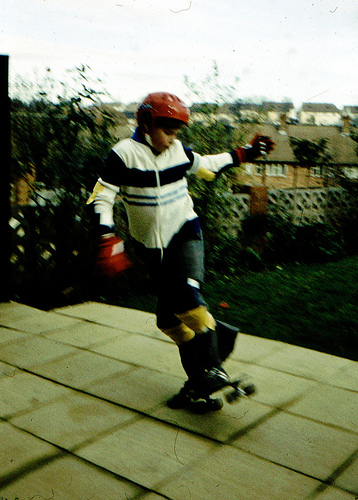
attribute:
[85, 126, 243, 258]
sweater — long sleeved, striped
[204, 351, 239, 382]
shoe — boy's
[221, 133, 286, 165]
hand — his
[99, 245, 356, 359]
grass — green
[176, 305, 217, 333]
kneepad — yellow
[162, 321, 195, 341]
kneepad — yellow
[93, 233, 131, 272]
glove — red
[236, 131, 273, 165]
glove — red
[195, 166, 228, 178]
patch — yellow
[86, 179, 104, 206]
patch — yellow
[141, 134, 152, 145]
strap — white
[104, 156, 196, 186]
stripe — black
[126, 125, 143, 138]
collar — blue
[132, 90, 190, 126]
helmet — red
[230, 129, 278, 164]
gloves — black, red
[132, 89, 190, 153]
helmet — rde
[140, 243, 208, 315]
shorts — black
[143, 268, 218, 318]
kneepads — yellow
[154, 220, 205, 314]
jeans — blue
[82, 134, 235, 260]
sweatshirt — white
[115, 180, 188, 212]
stripes — blue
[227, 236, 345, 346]
path — yellow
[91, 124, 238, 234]
jacket — blue,white and yellow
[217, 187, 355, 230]
fence — white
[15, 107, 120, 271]
tree — old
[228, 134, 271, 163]
glove — red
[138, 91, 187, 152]
head — boy's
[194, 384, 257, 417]
wheels — skateboard's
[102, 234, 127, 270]
hand — boy's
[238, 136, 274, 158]
hand — boy's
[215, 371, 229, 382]
stripe — white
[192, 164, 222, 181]
elbow — boy's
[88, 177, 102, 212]
elbow — boy's